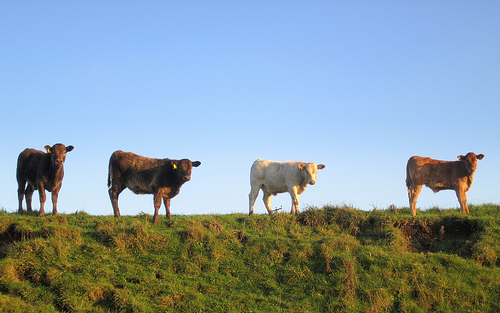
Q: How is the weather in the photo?
A: It is cloudless.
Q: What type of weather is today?
A: It is cloudless.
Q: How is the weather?
A: It is cloudless.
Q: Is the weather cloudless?
A: Yes, it is cloudless.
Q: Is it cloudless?
A: Yes, it is cloudless.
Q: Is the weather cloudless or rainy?
A: It is cloudless.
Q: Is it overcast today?
A: No, it is cloudless.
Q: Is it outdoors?
A: Yes, it is outdoors.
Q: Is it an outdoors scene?
A: Yes, it is outdoors.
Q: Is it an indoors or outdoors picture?
A: It is outdoors.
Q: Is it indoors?
A: No, it is outdoors.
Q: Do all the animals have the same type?
A: Yes, all the animals are cows.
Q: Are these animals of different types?
A: No, all the animals are cows.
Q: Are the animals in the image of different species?
A: No, all the animals are cows.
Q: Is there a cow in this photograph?
A: Yes, there is a cow.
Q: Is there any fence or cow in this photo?
A: Yes, there is a cow.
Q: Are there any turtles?
A: No, there are no turtles.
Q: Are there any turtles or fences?
A: No, there are no turtles or fences.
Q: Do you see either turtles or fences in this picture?
A: No, there are no turtles or fences.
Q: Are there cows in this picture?
A: Yes, there is a cow.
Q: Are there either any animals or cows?
A: Yes, there is a cow.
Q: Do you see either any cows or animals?
A: Yes, there is a cow.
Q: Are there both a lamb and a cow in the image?
A: No, there is a cow but no lambs.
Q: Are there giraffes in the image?
A: No, there are no giraffes.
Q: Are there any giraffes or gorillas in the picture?
A: No, there are no giraffes or gorillas.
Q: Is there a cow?
A: Yes, there is a cow.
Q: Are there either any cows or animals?
A: Yes, there is a cow.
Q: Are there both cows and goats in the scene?
A: No, there is a cow but no goats.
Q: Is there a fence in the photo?
A: No, there are no fences.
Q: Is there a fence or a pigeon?
A: No, there are no fences or pigeons.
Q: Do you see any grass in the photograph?
A: Yes, there is grass.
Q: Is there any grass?
A: Yes, there is grass.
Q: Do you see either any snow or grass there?
A: Yes, there is grass.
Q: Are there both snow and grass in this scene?
A: No, there is grass but no snow.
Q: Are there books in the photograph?
A: No, there are no books.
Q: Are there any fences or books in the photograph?
A: No, there are no books or fences.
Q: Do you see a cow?
A: Yes, there is a cow.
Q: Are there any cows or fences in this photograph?
A: Yes, there is a cow.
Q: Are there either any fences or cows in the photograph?
A: Yes, there is a cow.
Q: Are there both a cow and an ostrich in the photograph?
A: No, there is a cow but no ostriches.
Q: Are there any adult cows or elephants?
A: Yes, there is an adult cow.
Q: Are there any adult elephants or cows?
A: Yes, there is an adult cow.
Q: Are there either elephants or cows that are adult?
A: Yes, the cow is adult.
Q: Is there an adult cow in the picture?
A: Yes, there is an adult cow.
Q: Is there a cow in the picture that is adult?
A: Yes, there is a cow that is adult.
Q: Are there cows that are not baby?
A: Yes, there is a adult cow.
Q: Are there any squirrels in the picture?
A: No, there are no squirrels.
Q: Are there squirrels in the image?
A: No, there are no squirrels.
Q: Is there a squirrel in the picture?
A: No, there are no squirrels.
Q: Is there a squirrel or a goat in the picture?
A: No, there are no squirrels or goats.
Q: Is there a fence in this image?
A: No, there are no fences.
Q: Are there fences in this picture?
A: No, there are no fences.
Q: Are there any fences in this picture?
A: No, there are no fences.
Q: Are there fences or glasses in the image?
A: No, there are no fences or glasses.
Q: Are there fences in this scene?
A: No, there are no fences.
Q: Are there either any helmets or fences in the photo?
A: No, there are no fences or helmets.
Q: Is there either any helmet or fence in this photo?
A: No, there are no fences or helmets.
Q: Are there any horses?
A: No, there are no horses.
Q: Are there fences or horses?
A: No, there are no horses or fences.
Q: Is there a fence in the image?
A: No, there are no fences.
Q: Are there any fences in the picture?
A: No, there are no fences.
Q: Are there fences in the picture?
A: No, there are no fences.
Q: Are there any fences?
A: No, there are no fences.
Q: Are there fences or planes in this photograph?
A: No, there are no fences or planes.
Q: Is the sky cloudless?
A: Yes, the sky is cloudless.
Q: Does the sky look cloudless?
A: Yes, the sky is cloudless.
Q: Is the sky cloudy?
A: No, the sky is cloudless.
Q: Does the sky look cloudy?
A: No, the sky is cloudless.